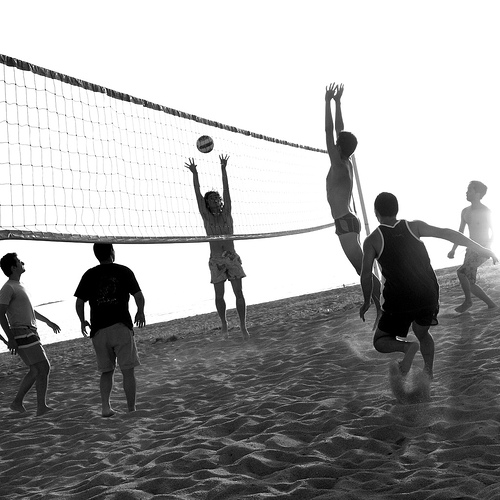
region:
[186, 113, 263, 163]
the volleyball is in the air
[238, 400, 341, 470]
the sand is bumpy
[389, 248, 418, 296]
the mans shirt is black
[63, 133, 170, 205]
the net is up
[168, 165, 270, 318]
the man is jumping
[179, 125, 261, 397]
the man is jumping for the ball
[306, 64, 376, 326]
this man is jumping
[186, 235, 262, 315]
the man has swim trunks on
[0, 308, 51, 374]
the mans swim trunks are striped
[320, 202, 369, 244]
the man is wearing shorts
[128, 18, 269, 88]
clear sky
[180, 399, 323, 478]
sand on beach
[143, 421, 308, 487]
sand with footprints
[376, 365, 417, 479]
shadow of person standing on sand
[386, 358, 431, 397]
sand being kicked into air by foot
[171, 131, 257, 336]
man jumping to reach for ball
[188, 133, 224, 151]
volleyball in the air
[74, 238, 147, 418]
man standing idly by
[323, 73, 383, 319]
second man jumping in the air reaching for ball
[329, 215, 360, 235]
speedo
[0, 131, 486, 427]
six young men playing volley ball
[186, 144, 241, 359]
a man jumping in the air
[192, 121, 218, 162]
a volley ball in the air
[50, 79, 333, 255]
a volley ball net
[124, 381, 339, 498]
a sandy beach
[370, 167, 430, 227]
a man with short hair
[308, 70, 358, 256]
a man with his arms raised over his head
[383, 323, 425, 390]
a man with one foot raised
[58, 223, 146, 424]
a man standing on a beach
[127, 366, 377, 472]
tracks in the sand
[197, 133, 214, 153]
volleyball in the air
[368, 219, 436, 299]
tank top has white seams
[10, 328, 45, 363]
striped bathing suit shorts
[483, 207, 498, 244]
sun shining behind the man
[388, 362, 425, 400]
sand is being kicked up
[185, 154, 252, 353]
volleyball player jumping in the air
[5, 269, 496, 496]
sand is covered in footprints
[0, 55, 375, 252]
volleyball net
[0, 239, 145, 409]
two men watching the play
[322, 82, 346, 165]
man's arms are straight up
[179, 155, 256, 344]
Man jumping in the air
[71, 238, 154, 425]
Man standing in the sand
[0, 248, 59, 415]
Man standng in the sand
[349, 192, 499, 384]
Man running in the sand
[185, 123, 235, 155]
Ball in the air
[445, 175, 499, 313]
Man standing in the sand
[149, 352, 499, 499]
Ripples in the sand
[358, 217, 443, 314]
Man wearing a black tanktop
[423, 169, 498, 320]
Sun shining on man